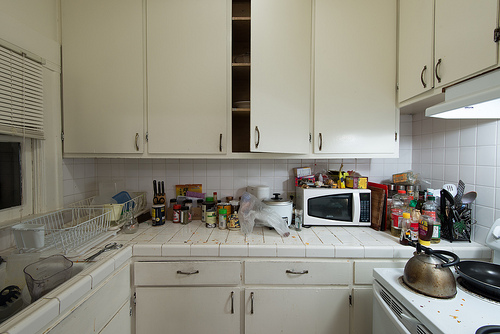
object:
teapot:
[402, 241, 460, 300]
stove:
[369, 225, 500, 333]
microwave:
[296, 186, 374, 227]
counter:
[136, 206, 486, 259]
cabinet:
[146, 2, 315, 160]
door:
[246, 0, 315, 156]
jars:
[167, 191, 240, 233]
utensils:
[440, 181, 476, 243]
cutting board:
[370, 180, 389, 231]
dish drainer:
[9, 205, 117, 259]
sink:
[0, 238, 87, 330]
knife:
[151, 178, 158, 197]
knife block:
[152, 193, 167, 210]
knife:
[158, 181, 163, 197]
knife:
[161, 182, 168, 197]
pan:
[459, 256, 500, 302]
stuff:
[292, 164, 369, 190]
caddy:
[446, 207, 474, 241]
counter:
[66, 216, 156, 272]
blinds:
[0, 36, 46, 140]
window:
[0, 41, 39, 223]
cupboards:
[63, 5, 398, 161]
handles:
[253, 125, 262, 150]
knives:
[152, 179, 167, 197]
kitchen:
[5, 152, 473, 231]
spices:
[169, 198, 193, 228]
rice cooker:
[261, 192, 294, 230]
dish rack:
[66, 190, 150, 230]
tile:
[126, 226, 399, 256]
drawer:
[132, 258, 377, 287]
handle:
[177, 268, 201, 279]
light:
[425, 72, 499, 120]